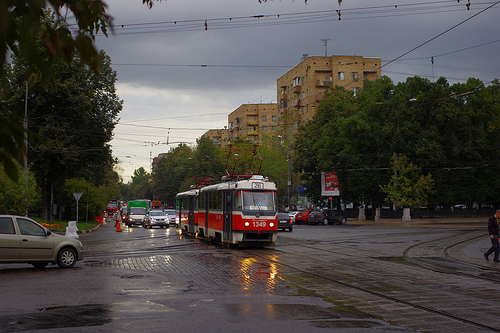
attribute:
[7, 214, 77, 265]
car — stopped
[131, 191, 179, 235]
vehicles — motor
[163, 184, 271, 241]
train — electric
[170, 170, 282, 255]
train — moving, red, white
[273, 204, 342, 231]
automobiles — parked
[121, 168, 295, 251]
traffic — moving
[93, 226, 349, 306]
street — wet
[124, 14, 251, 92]
clouds — dark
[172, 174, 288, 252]
train — electric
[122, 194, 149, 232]
vehicle — green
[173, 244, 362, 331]
street — wet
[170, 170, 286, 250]
tram — red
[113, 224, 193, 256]
street — wet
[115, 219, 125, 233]
cone — orange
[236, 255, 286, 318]
reflection — headlights